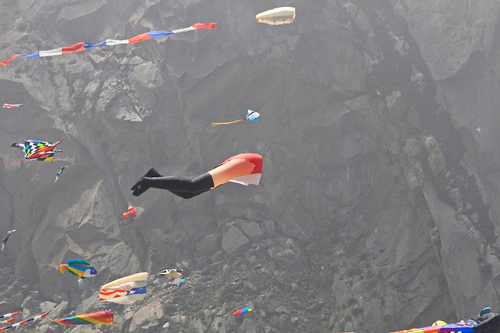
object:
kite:
[8, 136, 66, 163]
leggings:
[129, 167, 212, 199]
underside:
[227, 169, 264, 191]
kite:
[163, 263, 198, 287]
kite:
[0, 101, 29, 113]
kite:
[129, 152, 261, 200]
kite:
[242, 107, 267, 124]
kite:
[53, 252, 100, 281]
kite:
[255, 7, 303, 27]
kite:
[116, 197, 148, 222]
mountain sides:
[29, 179, 145, 301]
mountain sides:
[421, 7, 498, 320]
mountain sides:
[106, 3, 420, 330]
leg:
[131, 153, 264, 200]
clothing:
[213, 145, 269, 186]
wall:
[328, 133, 453, 241]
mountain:
[0, 0, 499, 332]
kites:
[5, 22, 225, 66]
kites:
[49, 164, 74, 184]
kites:
[219, 296, 258, 320]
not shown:
[315, 3, 499, 234]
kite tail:
[204, 114, 243, 129]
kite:
[46, 309, 113, 327]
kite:
[97, 269, 191, 306]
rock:
[305, 300, 323, 315]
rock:
[126, 56, 168, 101]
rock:
[425, 129, 445, 153]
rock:
[228, 279, 242, 289]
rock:
[53, 175, 124, 244]